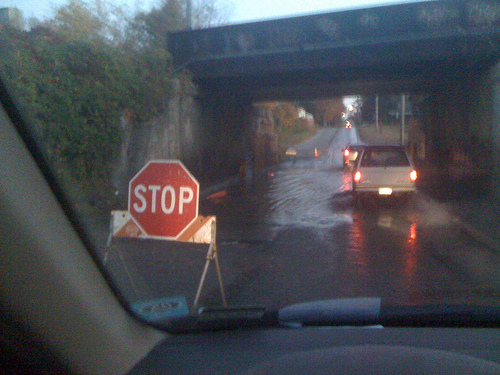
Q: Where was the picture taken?
A: In a car.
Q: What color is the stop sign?
A: Red.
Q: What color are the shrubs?
A: Green.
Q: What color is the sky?
A: Blue.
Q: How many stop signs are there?
A: One.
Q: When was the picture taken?
A: Daytime.